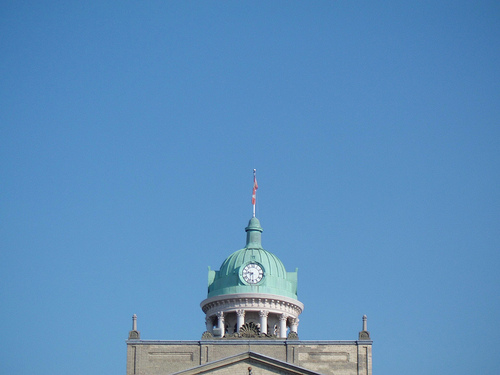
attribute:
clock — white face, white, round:
[242, 262, 268, 287]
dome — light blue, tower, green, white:
[214, 245, 295, 297]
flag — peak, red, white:
[251, 176, 260, 196]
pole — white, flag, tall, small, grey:
[252, 163, 261, 230]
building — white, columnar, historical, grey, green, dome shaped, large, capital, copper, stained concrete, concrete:
[126, 335, 367, 374]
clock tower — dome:
[206, 219, 307, 332]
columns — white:
[215, 313, 296, 334]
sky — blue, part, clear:
[10, 6, 500, 367]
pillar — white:
[235, 308, 244, 330]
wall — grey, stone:
[130, 344, 361, 375]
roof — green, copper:
[217, 231, 289, 300]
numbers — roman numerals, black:
[243, 264, 264, 284]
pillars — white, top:
[217, 311, 291, 335]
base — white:
[200, 294, 308, 311]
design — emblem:
[243, 326, 261, 343]